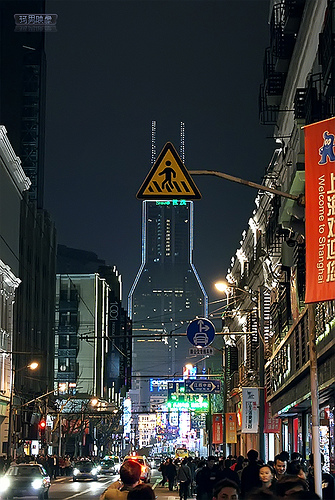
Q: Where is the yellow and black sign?
A: Hanging in the center.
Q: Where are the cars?
A: On the street.